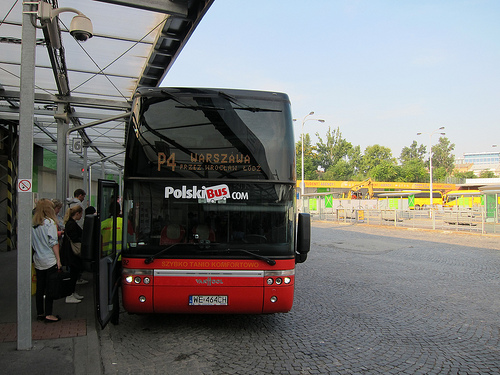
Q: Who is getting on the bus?
A: People.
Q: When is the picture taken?
A: Daytime.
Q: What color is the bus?
A: Red.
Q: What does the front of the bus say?
A: Polskibus.com.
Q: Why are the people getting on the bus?
A: Going somewhere.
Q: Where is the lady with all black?
A: Near the bus.